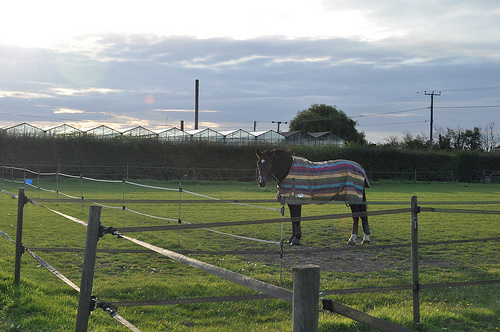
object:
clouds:
[71, 25, 428, 95]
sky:
[0, 0, 496, 129]